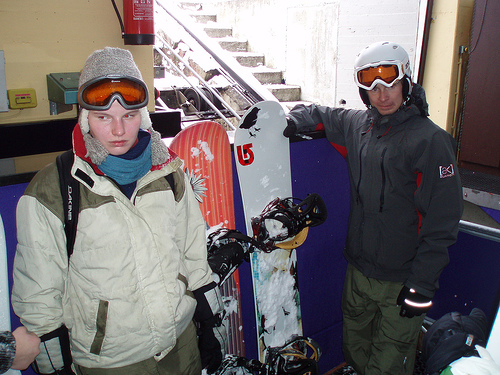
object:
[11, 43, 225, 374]
snowboarder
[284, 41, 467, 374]
snowboarder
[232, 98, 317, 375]
snowboard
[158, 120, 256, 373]
snowboard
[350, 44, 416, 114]
helmet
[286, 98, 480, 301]
jacket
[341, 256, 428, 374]
pants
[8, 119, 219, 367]
coat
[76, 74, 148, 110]
googles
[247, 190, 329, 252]
binding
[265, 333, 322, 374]
binding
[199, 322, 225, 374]
glove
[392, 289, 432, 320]
glove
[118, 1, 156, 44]
extinguisher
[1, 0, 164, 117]
wall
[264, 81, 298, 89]
snow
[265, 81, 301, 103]
stairs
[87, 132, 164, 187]
scarf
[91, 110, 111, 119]
eyes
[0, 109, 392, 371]
wall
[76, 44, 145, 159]
head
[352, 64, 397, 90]
goggles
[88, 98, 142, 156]
face